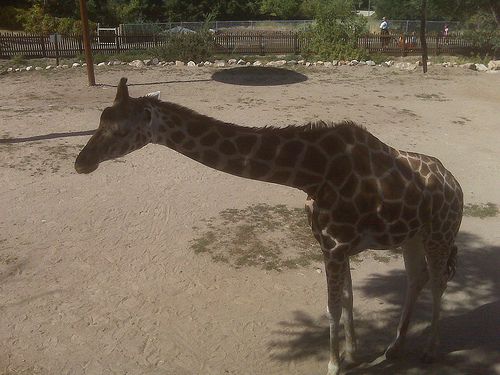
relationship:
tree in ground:
[417, 8, 429, 79] [6, 68, 498, 369]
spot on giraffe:
[233, 132, 258, 157] [75, 76, 464, 375]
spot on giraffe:
[349, 139, 370, 179] [75, 76, 464, 375]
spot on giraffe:
[408, 166, 431, 193] [75, 76, 464, 375]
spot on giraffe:
[426, 190, 449, 217] [78, 67, 410, 304]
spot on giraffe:
[431, 210, 447, 233] [75, 76, 464, 375]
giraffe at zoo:
[75, 76, 464, 375] [0, 28, 498, 373]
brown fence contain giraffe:
[0, 31, 497, 65] [75, 76, 464, 375]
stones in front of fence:
[1, 56, 496, 76] [0, 20, 498, 57]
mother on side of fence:
[379, 17, 390, 49] [1, 26, 498, 63]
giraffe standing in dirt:
[75, 76, 464, 375] [0, 266, 500, 373]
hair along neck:
[218, 119, 365, 165] [144, 90, 334, 195]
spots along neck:
[166, 117, 295, 173] [150, 97, 318, 191]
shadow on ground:
[278, 231, 498, 361] [6, 68, 498, 369]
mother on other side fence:
[379, 17, 390, 49] [1, 31, 498, 66]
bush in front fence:
[282, 18, 379, 53] [4, 33, 496, 59]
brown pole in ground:
[66, 3, 112, 81] [3, 76, 443, 106]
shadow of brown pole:
[109, 63, 308, 89] [78, 0, 96, 86]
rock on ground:
[320, 58, 328, 68] [6, 68, 498, 369]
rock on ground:
[297, 58, 304, 63] [6, 68, 498, 369]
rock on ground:
[304, 58, 311, 66] [6, 68, 498, 369]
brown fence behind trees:
[0, 31, 497, 68] [20, 5, 95, 59]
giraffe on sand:
[75, 76, 464, 375] [7, 49, 496, 367]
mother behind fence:
[379, 17, 390, 49] [0, 32, 499, 55]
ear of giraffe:
[115, 76, 132, 106] [75, 76, 464, 375]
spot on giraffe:
[200, 130, 220, 145] [75, 76, 464, 375]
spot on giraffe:
[324, 153, 351, 188] [75, 76, 464, 375]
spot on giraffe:
[404, 180, 421, 208] [75, 76, 464, 375]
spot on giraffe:
[440, 220, 453, 233] [75, 76, 464, 375]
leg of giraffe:
[322, 253, 348, 373] [75, 76, 464, 375]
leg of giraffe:
[341, 255, 356, 353] [75, 76, 464, 375]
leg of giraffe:
[377, 236, 412, 367] [75, 76, 464, 375]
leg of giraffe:
[419, 249, 459, 367] [75, 76, 464, 375]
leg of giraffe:
[340, 256, 363, 371] [75, 76, 464, 375]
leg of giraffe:
[396, 240, 429, 343] [75, 76, 464, 375]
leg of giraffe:
[424, 244, 448, 343] [75, 76, 464, 375]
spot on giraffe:
[383, 182, 428, 207] [75, 76, 464, 375]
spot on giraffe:
[303, 148, 333, 178] [75, 76, 464, 375]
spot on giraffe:
[378, 171, 409, 201] [75, 76, 464, 375]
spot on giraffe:
[381, 175, 405, 197] [57, 65, 475, 357]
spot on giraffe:
[381, 164, 402, 199] [71, 110, 479, 375]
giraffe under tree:
[46, 39, 475, 374] [37, 64, 68, 96]